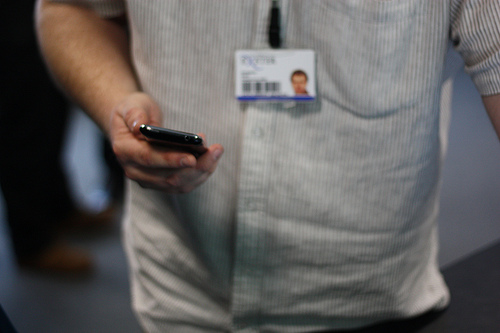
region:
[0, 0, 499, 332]
stock photo, or stock photo wannabe.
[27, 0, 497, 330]
prototypical worker dude, in uniform shirt+name tag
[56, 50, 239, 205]
worker works mobile phone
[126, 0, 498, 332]
striped uniform shirt over minimal beer gut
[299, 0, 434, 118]
saggy pocket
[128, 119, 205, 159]
reflection off thumbnail, top of cellphone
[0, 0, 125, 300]
another worker dude's legs, blurred out via photoshop, in background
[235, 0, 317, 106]
name tag on black, possibly elastic, twisty rope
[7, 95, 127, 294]
worker dude behind has no head or torso, dark slacks, brown shoes, w/ a light source behind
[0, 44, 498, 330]
background [grey carpet, greyish white walls] of, or made to look like, typical blue collar workroom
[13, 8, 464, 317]
this guy is messing with his cellphone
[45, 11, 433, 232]
the worker is making a call on his phone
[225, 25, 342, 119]
this is the man's ID badge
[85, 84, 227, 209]
his cellphone is sitting in his hand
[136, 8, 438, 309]
he is wearing a grey striped shirt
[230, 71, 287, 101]
his ID has a bar code on it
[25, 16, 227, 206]
this is the man's arm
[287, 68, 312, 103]
a picture of a man's face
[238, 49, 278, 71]
this is the name of the worker's company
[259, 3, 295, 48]
this is a black string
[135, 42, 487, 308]
this is a man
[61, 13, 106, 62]
the man is light skinned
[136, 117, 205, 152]
this is a phone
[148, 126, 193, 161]
the phone is black in color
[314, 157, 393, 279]
this is a shirt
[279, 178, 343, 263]
the shirt is white in color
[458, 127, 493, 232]
this is the wall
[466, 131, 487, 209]
the wall is white in color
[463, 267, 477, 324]
this is the floor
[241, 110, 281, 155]
part of a button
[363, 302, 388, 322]
edge of a shirt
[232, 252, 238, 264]
part of a shirt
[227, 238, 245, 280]
part of a shiort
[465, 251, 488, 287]
part of a table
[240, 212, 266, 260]
part of a buttin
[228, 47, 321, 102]
A tag in the photo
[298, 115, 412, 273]
A blue and white striped shirt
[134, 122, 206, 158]
A mobile phone in the photo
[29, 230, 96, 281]
A brown shoe in the background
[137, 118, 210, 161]
A mobile phone black in color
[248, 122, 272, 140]
A button on the shirt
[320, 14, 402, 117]
A pocket on the shirt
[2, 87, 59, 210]
A black trouser in the background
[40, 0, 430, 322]
A man standing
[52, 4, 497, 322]
A man holding a mobile phone